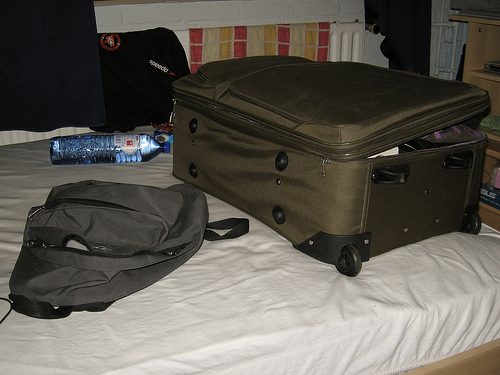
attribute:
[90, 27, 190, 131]
shirt — black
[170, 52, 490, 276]
suitcase — brown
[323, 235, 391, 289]
wheel — black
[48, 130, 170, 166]
bottle — blue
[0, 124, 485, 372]
sheet — white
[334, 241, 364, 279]
wheels — black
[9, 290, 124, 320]
handle — black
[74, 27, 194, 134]
shirt — black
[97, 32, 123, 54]
emblem — red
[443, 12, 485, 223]
shelve — wooden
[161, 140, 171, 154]
cap — blue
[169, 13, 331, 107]
curtain — yellow